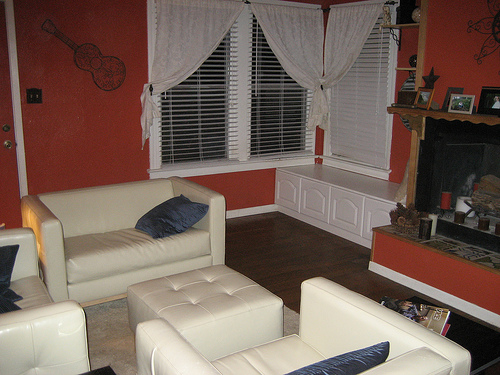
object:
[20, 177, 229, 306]
love seat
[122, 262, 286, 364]
ottoman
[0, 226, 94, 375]
chair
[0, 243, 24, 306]
pillow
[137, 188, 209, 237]
pillow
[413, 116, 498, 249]
fireplace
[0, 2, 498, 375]
living room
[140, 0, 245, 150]
curtains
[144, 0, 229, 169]
window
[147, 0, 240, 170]
blinds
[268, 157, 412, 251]
window seat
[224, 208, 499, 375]
floors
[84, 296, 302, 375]
carpet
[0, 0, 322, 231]
walls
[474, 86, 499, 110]
pictures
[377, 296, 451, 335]
magazines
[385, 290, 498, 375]
table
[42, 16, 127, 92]
decoration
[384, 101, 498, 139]
shelf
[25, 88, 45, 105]
light switch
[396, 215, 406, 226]
pinecones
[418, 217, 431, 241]
bowl